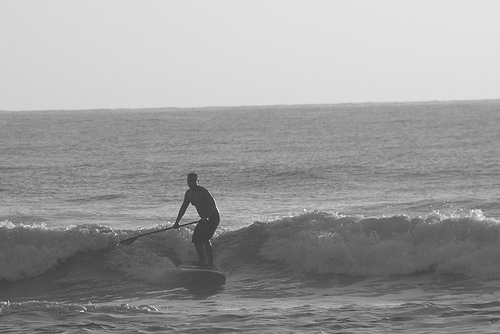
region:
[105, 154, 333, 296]
The man is surfing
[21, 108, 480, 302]
The water is uncolored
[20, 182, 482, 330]
riding on a wave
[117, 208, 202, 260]
holding on to a rope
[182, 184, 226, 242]
The man has no shirt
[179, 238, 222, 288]
standing on a board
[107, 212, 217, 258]
He is holding a net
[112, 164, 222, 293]
trying to catch something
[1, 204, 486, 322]
the waves produce foam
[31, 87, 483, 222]
The ocean is very long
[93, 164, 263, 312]
MAN IS ON SURFBOARD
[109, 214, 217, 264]
MAN IS HOLDING OAR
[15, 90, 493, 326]
MAN IS IN OCEAN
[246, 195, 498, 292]
WAVES BREAKING IN OCEAN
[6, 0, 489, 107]
SKY IN BACKGROUND IS GRAY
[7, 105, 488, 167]
COLOR OF WATER IS GRAY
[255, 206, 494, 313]
WAVES ARE FROTHY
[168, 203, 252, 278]
MANS KNEES ARE SLIGHTLY BENT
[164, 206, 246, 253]
MAN IS WEARING KNEE-LENGTH SWIM TRUNKS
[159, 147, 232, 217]
MAN HAS SHORT HAIR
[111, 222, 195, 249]
a long oar for paddling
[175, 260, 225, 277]
a surfboard in the water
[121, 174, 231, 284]
a man paddling a surfboard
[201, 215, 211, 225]
the light reflecting off a watch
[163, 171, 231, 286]
a man standing on water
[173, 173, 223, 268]
a man wearing boardshorts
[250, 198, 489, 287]
a wave crashing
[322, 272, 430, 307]
some bubbles in the water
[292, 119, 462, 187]
water covered in ripples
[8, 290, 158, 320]
a patch of rough water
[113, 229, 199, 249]
dark paddle in man's hand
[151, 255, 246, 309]
frontward facing surfboard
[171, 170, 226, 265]
man standing on surfboard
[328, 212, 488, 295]
white foam ontop of water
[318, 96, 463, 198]
large patch of ocean water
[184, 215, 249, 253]
man's swimming trunks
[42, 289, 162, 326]
small waves on the water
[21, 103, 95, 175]
dark water off in the distance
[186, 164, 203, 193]
head on man who's surfing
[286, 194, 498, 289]
large portion of wave on right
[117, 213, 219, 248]
MAN IS HOLDING AN OAR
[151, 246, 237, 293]
SURF BOARD IS ON THE WATER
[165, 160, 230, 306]
MAN IS ON THE SURF BOARD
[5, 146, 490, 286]
MAN IS RIDING A WAVE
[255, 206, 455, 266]
WHITE CAPS ARE ON TOP OF THE WAVES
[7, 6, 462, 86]
NO CLOUDS ARE IN THE SKY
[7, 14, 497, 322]
PICTURE IS PRINTED IN BLACK AND WHITE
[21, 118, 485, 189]
THERE ARE NO BOATS IN THE WATER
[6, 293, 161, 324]
FOAM IS ON TOP OF THE WATER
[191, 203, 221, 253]
MAN IS WEARING SHORTS